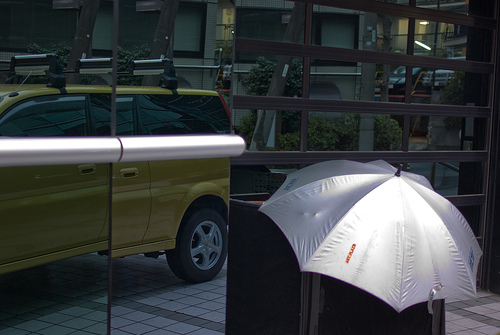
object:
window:
[235, 1, 306, 47]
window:
[169, 2, 205, 53]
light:
[115, 94, 230, 136]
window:
[306, 58, 406, 105]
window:
[406, 110, 488, 152]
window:
[304, 108, 402, 153]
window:
[309, 3, 408, 55]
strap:
[426, 288, 437, 317]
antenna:
[15, 66, 34, 93]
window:
[409, 70, 471, 95]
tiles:
[142, 315, 178, 329]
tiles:
[447, 308, 476, 317]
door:
[109, 95, 150, 251]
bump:
[311, 209, 326, 219]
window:
[113, 93, 234, 138]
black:
[395, 168, 404, 173]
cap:
[391, 164, 404, 175]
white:
[353, 206, 387, 219]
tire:
[164, 204, 229, 284]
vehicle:
[114, 73, 232, 284]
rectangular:
[407, 115, 460, 152]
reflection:
[0, 85, 108, 276]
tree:
[240, 54, 312, 129]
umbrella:
[257, 159, 484, 317]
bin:
[224, 189, 446, 334]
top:
[393, 163, 404, 177]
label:
[343, 244, 358, 265]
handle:
[118, 169, 138, 179]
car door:
[0, 92, 110, 276]